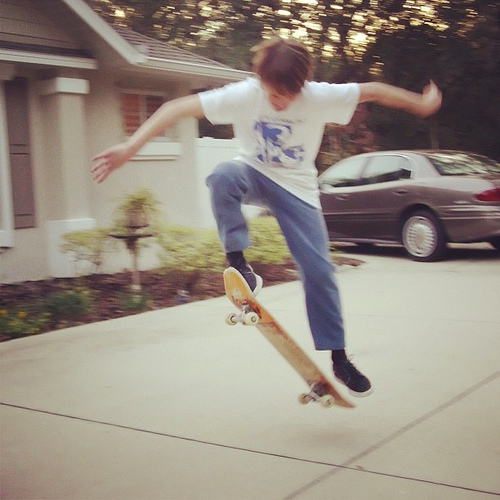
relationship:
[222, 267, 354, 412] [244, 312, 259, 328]
skateboard has polyurethane wheels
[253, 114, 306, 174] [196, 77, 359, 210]
blue art print on boys white t-shirt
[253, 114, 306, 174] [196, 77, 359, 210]
blue art design printed on boys t-shirt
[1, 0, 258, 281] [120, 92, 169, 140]
house has a jalousie type window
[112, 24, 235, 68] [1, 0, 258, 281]
cement or clay roof tiles are practical for a house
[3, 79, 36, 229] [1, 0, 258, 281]
wood window trim helps look of a house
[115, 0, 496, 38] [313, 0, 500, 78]
sunlight is filtering through trees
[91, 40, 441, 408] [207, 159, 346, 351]
skateboarder wearing blue jeans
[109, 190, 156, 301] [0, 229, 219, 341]
decorative planter supplies are in front garden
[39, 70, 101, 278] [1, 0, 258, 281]
concrete columns are built into house design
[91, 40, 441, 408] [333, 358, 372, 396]
skateboarder is wearing black skateboard shoes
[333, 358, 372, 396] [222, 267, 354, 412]
skateboard shoes prevent slipping on the skateboard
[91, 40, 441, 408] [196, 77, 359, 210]
skateboarder wearing a light colored shirt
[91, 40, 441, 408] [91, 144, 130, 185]
skateboarder using h hands for balance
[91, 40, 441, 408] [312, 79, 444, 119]
skateboarder is using his arms and hands for balance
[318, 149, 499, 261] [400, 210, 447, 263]
family car has standard wheels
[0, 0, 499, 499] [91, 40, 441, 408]
an action photo of a skateboarder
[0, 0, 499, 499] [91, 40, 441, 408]
this is an outside photo of a skateboarder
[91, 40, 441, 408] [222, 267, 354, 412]
young boy is practicing his skill on a skateboard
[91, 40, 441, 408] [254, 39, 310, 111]
skateboarder not wearing head protection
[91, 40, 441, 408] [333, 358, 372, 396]
young boy is wearing black skateboard shoes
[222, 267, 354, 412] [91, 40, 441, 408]
skateboard customized by skateboarder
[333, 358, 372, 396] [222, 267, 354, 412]
skateboard shoes prevent slipping on skateboard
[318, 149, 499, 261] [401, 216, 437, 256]
car has four custom silver wheels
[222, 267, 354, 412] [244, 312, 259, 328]
skateboard has four polyurethane wheels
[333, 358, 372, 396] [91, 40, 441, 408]
skateboard shoes help keep skateboarder safe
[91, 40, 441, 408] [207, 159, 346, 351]
skateboarder wearing tough blue jeans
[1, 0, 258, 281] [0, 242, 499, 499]
house has a circular driveway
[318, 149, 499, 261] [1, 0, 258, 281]
family car parked at home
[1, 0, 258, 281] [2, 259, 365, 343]
home has a planter in front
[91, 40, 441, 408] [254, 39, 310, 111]
skateboarder should wear a helmet on his head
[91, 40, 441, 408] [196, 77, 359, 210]
skateboarder wearing a t-shirt to stay cool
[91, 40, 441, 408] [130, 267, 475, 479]
skateboarder on sidewalk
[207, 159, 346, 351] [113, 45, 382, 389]
blue jeans on boy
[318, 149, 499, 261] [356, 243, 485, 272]
car parked in driveway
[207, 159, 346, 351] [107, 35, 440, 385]
blue jeans take on boy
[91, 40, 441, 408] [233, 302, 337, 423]
young boy on board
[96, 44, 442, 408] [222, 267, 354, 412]
boy on skateboard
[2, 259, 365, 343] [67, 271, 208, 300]
front garden has dirt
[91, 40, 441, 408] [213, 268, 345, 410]
skateboarder on skateboard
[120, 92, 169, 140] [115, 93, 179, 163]
indoor light on window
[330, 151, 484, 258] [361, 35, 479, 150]
car by treess